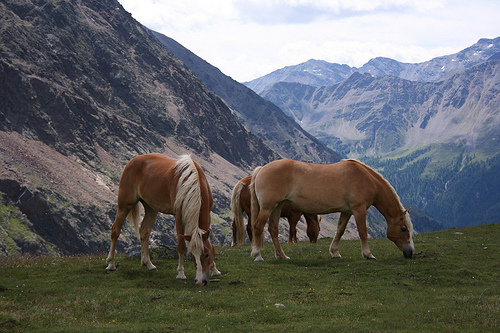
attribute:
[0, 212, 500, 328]
grass — brown, short, green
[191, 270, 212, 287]
nose — black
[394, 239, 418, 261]
nose — black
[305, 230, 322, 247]
nose — black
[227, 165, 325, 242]
horse — brown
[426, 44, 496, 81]
snow — white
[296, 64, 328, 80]
snow — white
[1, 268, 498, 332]
grass — green, short, brown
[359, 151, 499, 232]
trees — green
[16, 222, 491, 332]
grass — green, short, brown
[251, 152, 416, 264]
horse — brown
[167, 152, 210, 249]
mane — light brown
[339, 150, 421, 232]
mane — light brown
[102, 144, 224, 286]
horse — brown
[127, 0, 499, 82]
clouds — white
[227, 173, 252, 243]
horse — brown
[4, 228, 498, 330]
grass — short, green, brown, lush, full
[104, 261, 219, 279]
hooves — white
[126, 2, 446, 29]
clouds — white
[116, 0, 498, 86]
sky — blue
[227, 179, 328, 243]
horse — brown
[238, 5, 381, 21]
sky — blue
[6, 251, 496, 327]
grass — green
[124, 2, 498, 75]
cloud — white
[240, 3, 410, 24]
sky — blue